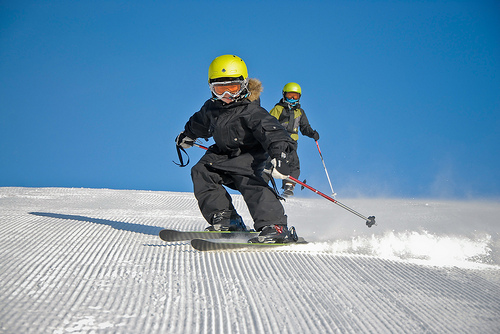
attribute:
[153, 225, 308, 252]
skiis — short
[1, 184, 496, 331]
slope —  white , snowy 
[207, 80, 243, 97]
goggles — white rimmed 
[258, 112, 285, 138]
pocket — black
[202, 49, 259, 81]
yellow helmet — yellow 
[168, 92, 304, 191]
coat — black , fur trimmed 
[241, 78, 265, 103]
hood — fur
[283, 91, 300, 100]
goggles —  blue rimmed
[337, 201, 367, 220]
silver —  red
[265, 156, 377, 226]
ski pole — silver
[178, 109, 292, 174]
coat — black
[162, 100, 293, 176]
jacket — black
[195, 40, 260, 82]
helmet — yellow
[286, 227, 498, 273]
sfresh snow — fresh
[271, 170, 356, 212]
poles — gray, red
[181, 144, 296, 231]
black pants — black 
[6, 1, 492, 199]
sky — clear, blue